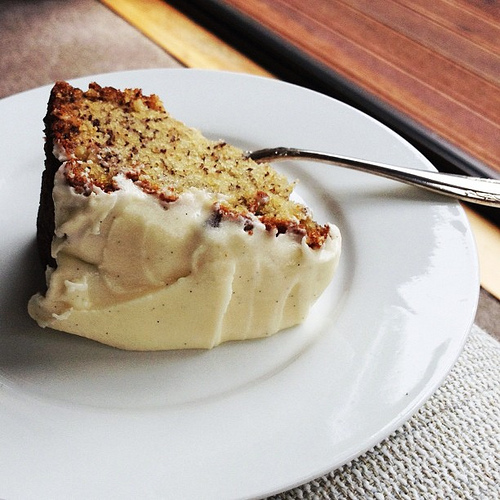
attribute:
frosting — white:
[25, 163, 344, 353]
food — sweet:
[24, 79, 344, 353]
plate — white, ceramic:
[3, 68, 479, 499]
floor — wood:
[223, 1, 499, 180]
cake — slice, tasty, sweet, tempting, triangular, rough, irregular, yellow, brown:
[25, 79, 342, 350]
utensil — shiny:
[243, 145, 498, 207]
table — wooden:
[1, 2, 499, 346]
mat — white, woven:
[257, 323, 498, 497]